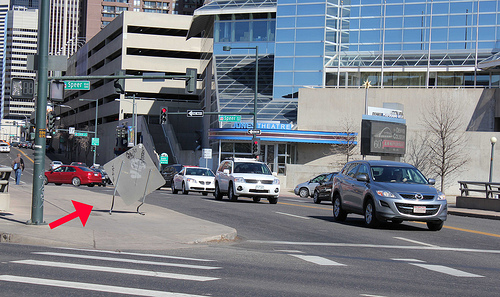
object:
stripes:
[1, 272, 208, 294]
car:
[44, 163, 105, 188]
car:
[213, 157, 281, 205]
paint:
[290, 253, 349, 268]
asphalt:
[6, 244, 498, 295]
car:
[331, 158, 449, 233]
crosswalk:
[0, 241, 234, 297]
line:
[293, 252, 348, 268]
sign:
[246, 128, 262, 134]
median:
[457, 179, 498, 201]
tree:
[421, 96, 468, 195]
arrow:
[47, 199, 94, 230]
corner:
[39, 217, 244, 254]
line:
[6, 258, 229, 286]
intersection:
[2, 206, 500, 297]